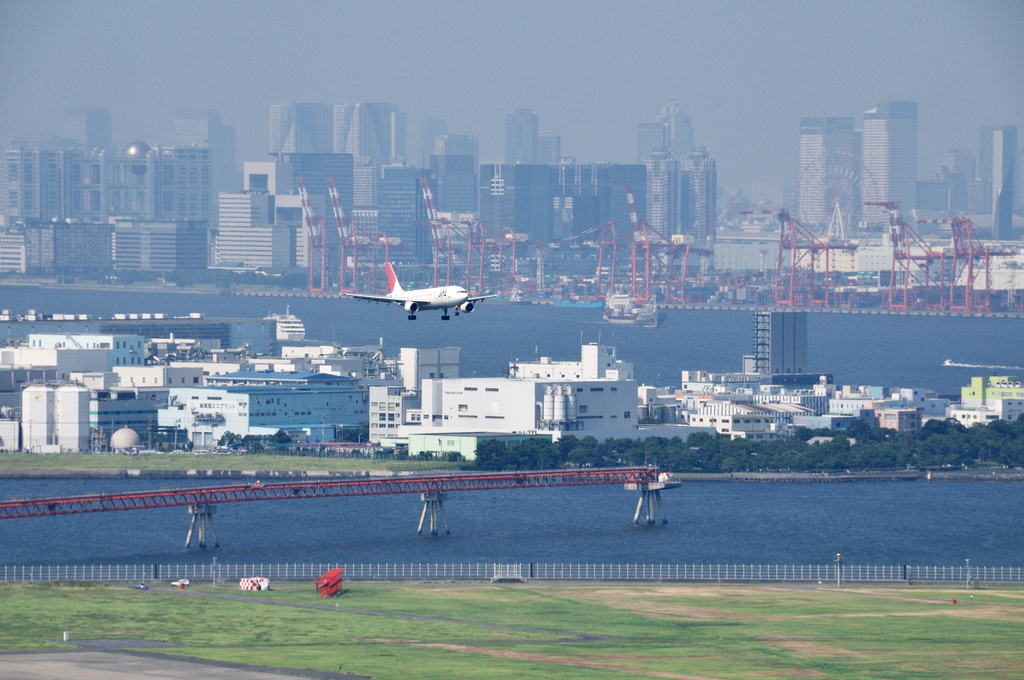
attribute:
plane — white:
[351, 256, 500, 320]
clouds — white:
[19, 8, 103, 62]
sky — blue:
[0, 7, 1021, 94]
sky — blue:
[3, 1, 1022, 100]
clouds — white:
[309, 29, 368, 77]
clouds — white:
[558, 55, 620, 85]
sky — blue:
[9, 1, 1022, 120]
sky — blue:
[3, 4, 1022, 161]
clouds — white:
[697, 41, 767, 77]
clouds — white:
[6, 5, 999, 100]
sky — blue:
[838, 27, 915, 67]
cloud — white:
[320, 17, 423, 75]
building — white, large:
[365, 343, 685, 460]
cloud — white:
[583, 69, 657, 114]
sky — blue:
[0, 2, 1022, 230]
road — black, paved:
[0, 644, 321, 677]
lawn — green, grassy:
[1, 578, 1022, 677]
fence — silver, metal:
[0, 552, 1013, 584]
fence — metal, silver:
[0, 555, 1019, 585]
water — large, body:
[0, 475, 1016, 561]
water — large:
[0, 472, 1021, 580]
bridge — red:
[0, 461, 668, 516]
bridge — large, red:
[2, 464, 650, 522]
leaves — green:
[901, 415, 943, 469]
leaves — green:
[618, 431, 656, 467]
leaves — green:
[539, 420, 565, 468]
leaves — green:
[487, 425, 514, 460]